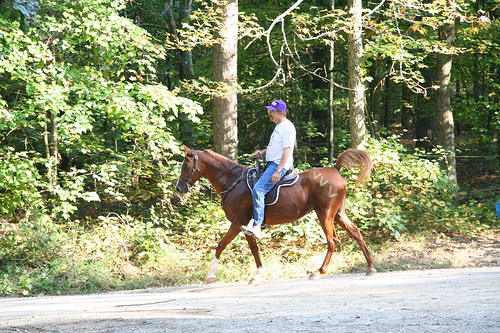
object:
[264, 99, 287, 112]
cap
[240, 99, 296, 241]
man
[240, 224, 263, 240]
shoe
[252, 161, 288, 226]
leg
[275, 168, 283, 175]
watch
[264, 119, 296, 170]
shirt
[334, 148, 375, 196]
tail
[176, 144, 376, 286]
horse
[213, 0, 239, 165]
trunk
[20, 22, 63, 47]
leaves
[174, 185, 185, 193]
nose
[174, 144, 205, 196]
head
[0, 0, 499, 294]
forest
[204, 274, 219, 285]
hooves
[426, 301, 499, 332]
gravel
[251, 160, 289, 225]
jeans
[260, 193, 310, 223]
harness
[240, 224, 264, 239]
foot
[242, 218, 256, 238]
stirrups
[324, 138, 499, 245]
bushes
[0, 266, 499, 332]
road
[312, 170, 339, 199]
pattern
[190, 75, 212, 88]
leaf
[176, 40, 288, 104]
branch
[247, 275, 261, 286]
hoof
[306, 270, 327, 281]
feet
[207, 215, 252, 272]
legs